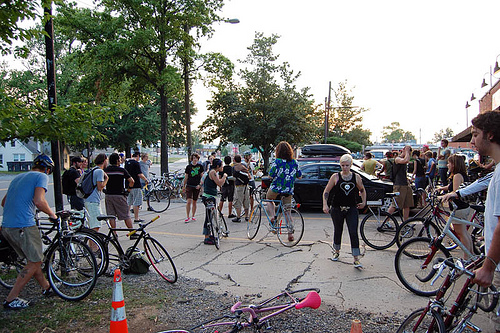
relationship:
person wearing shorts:
[180, 150, 205, 222] [183, 180, 200, 199]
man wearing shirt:
[104, 150, 141, 240] [104, 161, 130, 190]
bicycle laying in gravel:
[154, 285, 324, 332] [58, 263, 441, 330]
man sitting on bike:
[262, 137, 309, 251] [243, 191, 303, 249]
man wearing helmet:
[262, 137, 332, 263] [22, 150, 57, 177]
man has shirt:
[0, 150, 61, 312] [0, 167, 57, 228]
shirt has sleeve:
[0, 167, 57, 228] [32, 173, 54, 192]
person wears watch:
[430, 173, 492, 210] [452, 187, 461, 199]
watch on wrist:
[452, 187, 461, 199] [448, 190, 456, 200]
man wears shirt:
[457, 107, 499, 304] [469, 160, 497, 267]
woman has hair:
[312, 122, 415, 270] [324, 135, 355, 170]